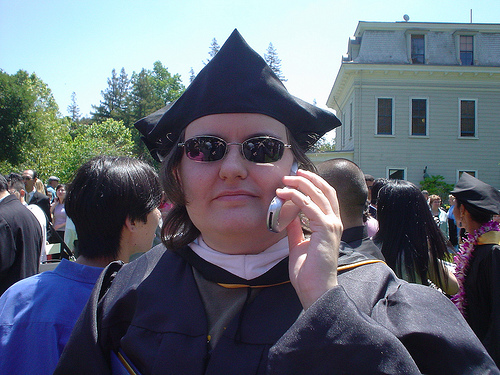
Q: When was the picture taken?
A: After graduation.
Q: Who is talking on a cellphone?
A: A graduate.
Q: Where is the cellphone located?
A: In the man's hand.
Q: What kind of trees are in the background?
A: Pine trees.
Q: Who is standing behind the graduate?
A: A man in blue.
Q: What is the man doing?
A: Talking on a phone.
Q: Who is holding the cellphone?
A: The woman in the hat and sunglasses is holding the cellphone.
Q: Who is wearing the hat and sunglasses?
A: The woman that is holding the cellphone.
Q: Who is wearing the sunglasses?
A: The woman that is wearing a hat and talking on the cellphone.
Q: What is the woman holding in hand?
A: A cellphone.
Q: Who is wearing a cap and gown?
A: The woman is wearing a cap and gown.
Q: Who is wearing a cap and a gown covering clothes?
A: The woman.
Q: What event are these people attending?
A: A graduation of some kind.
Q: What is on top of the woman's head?
A: A cap is on top of the woman's head.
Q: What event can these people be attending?
A: A graduation of some kind.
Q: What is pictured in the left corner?
A: Trees are.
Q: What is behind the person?
A: Building.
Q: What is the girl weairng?
A: Gown.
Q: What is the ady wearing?
A: Hat.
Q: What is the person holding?
A: Phone.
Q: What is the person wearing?
A: Sunglasses.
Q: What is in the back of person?
A: House.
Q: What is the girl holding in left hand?
A: Mobile.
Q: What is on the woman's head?
A: A black cap.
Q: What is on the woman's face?
A: Sun glasses.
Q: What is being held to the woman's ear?
A: A cell phone.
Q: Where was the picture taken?
A: A graduation ceremony.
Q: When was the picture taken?
A: Daytime.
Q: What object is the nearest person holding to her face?
A: A telephone.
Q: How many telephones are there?
A: One.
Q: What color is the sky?
A: Blue.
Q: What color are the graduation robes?
A: Black.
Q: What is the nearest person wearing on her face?
A: Sunglasses.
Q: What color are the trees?
A: Green.